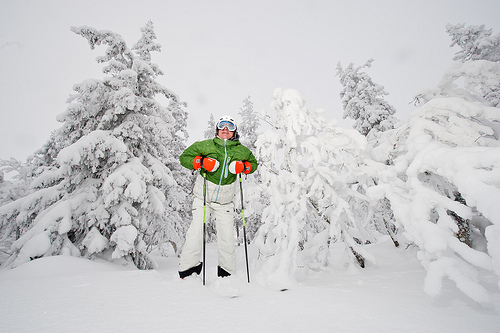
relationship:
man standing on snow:
[181, 116, 260, 285] [5, 256, 498, 332]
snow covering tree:
[0, 19, 497, 332] [30, 23, 196, 271]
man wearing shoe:
[181, 116, 260, 285] [181, 262, 206, 279]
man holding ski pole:
[181, 116, 260, 285] [233, 165, 255, 288]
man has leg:
[181, 116, 260, 285] [215, 208, 238, 279]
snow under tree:
[5, 256, 498, 332] [30, 23, 196, 271]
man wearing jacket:
[181, 116, 260, 285] [181, 141, 258, 207]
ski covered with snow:
[278, 286, 291, 296] [5, 256, 498, 332]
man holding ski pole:
[181, 116, 260, 285] [199, 165, 210, 295]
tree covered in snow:
[30, 23, 196, 271] [0, 19, 497, 332]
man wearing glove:
[181, 116, 260, 285] [228, 160, 253, 176]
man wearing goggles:
[181, 116, 260, 285] [218, 119, 235, 134]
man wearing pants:
[181, 116, 260, 285] [177, 198, 240, 280]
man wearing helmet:
[181, 116, 260, 285] [216, 111, 239, 125]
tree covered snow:
[30, 23, 196, 271] [5, 256, 498, 332]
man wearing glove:
[181, 116, 260, 285] [191, 153, 220, 174]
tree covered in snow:
[30, 23, 196, 271] [5, 256, 498, 332]